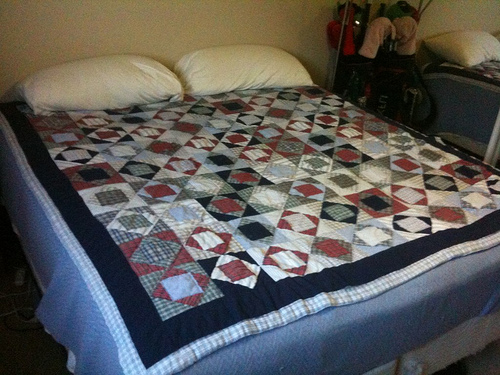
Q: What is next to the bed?
A: Mirror.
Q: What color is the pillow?
A: White.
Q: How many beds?
A: 1.